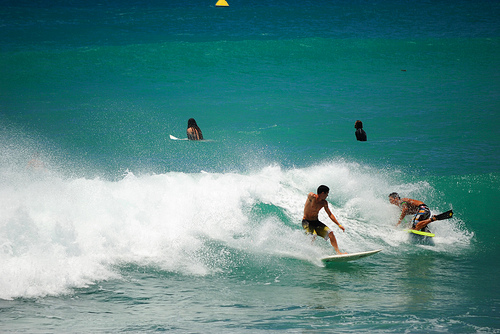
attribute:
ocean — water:
[59, 58, 139, 122]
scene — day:
[140, 54, 426, 215]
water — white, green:
[192, 61, 329, 110]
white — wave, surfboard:
[107, 202, 169, 234]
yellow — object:
[205, 1, 245, 11]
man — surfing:
[296, 178, 345, 258]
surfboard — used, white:
[310, 254, 375, 266]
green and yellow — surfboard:
[401, 217, 437, 244]